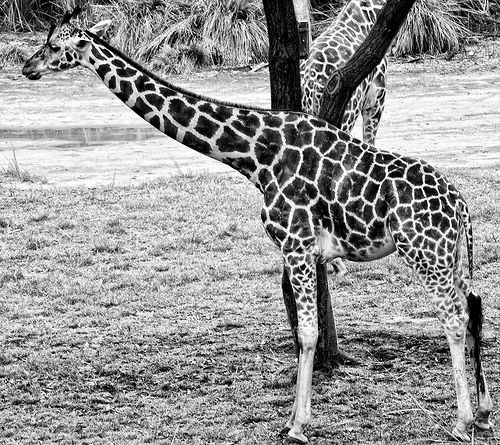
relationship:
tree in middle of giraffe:
[257, 0, 423, 372] [298, 1, 387, 151]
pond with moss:
[2, 81, 234, 178] [2, 79, 227, 196]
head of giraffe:
[20, 10, 109, 85] [17, 6, 495, 443]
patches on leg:
[456, 279, 466, 288] [267, 212, 317, 442]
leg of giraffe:
[401, 240, 470, 442] [17, 6, 495, 443]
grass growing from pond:
[0, 140, 499, 444] [0, 130, 205, 184]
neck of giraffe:
[89, 42, 270, 189] [17, 6, 495, 443]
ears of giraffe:
[86, 16, 114, 43] [17, 6, 495, 443]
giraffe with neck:
[17, 6, 495, 443] [87, 31, 249, 174]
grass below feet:
[0, 140, 499, 444] [231, 354, 363, 443]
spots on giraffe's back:
[319, 152, 356, 187] [293, 115, 387, 185]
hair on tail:
[462, 289, 486, 394] [456, 195, 481, 398]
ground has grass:
[0, 28, 297, 444] [297, 248, 447, 443]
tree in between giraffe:
[262, 0, 413, 369] [17, 6, 495, 443]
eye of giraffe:
[34, 24, 71, 82] [17, 7, 484, 377]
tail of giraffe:
[446, 197, 484, 392] [17, 7, 484, 377]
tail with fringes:
[446, 197, 484, 392] [465, 290, 482, 390]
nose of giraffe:
[22, 60, 33, 72] [17, 6, 495, 443]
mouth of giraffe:
[22, 68, 54, 78] [17, 6, 495, 443]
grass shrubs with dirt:
[0, 0, 499, 78] [176, 64, 268, 90]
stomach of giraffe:
[296, 173, 401, 258] [17, 6, 495, 443]